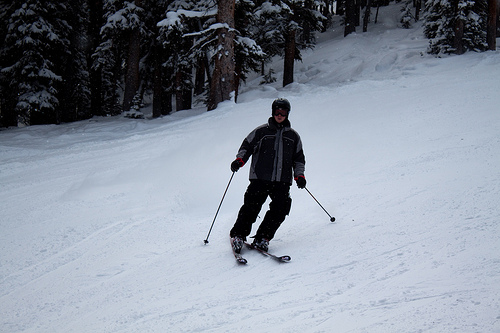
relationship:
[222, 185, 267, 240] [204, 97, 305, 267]
leg of person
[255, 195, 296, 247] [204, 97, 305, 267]
leg of person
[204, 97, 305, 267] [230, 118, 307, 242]
person wearing snow suit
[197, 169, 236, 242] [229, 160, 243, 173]
pole in hand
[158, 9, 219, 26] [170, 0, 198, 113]
snow covering tree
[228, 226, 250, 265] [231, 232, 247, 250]
ski on foot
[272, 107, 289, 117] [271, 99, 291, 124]
googles on head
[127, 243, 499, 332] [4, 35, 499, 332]
tracks in snow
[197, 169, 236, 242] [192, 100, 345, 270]
stick for skating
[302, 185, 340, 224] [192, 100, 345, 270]
stick for skating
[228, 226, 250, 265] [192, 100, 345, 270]
ski for skating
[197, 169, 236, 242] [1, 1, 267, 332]
pole on left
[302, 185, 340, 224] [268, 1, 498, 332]
pole on right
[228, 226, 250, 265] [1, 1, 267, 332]
ski on left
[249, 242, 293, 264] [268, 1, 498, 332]
ski on right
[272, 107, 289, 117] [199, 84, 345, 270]
goggles for ski